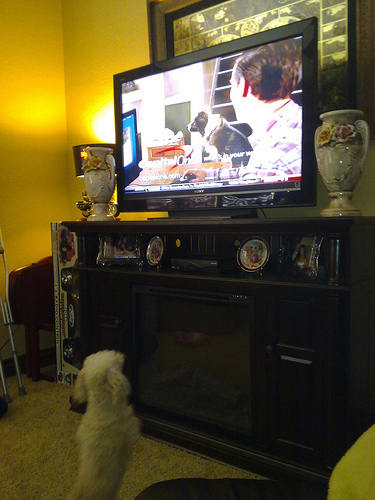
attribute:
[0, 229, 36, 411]
crutches — metal, silver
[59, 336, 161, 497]
dog — jumping, white, small, sitting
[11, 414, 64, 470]
carpet — light, white, beige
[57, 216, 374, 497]
entertainment center — dark, wood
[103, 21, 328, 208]
television — large, on, black, flat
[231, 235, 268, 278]
plate — small, decorative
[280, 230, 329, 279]
frame — silver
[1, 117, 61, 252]
wall — yellow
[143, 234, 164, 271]
china — small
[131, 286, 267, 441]
fireplace — electric